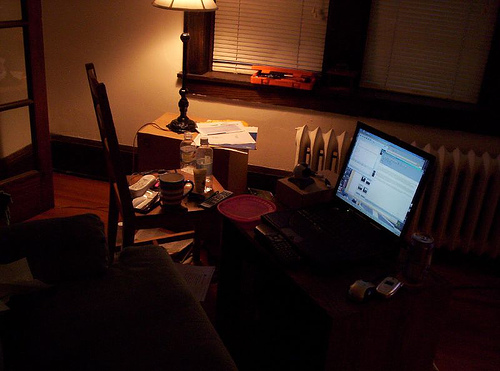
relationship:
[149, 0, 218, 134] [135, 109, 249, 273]
lamp on top of table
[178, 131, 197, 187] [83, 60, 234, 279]
bottle on top of chair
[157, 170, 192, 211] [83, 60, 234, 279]
coffee mug on top of chair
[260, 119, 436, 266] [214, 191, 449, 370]
laptop on top of desk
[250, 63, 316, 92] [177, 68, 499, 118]
tools sitting on window sill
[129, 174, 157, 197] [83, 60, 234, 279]
cordless phone on top of chair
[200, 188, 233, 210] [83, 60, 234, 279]
remote on top of chair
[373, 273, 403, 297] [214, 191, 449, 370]
cellphone on top of desk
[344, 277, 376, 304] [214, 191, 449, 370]
mouse on top of desk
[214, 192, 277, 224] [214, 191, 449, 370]
plate on top of desk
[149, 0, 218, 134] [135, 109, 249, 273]
lamp sitting on table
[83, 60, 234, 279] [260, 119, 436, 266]
chair next to laptop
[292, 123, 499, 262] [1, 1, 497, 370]
radiator inside of room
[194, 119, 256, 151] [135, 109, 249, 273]
papers on top of table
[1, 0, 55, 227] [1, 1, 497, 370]
door inside of room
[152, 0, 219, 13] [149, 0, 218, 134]
shade on top of lamp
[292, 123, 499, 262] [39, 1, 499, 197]
radiator mounted on wall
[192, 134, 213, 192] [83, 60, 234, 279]
bottle sitting on chair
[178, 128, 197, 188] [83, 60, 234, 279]
bottle sitting on chair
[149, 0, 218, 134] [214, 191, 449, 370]
lamp to left of desk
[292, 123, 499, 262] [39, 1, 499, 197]
radiator along wall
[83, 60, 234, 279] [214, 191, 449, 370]
chair left of desk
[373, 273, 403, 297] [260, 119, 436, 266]
cellphone next to laptop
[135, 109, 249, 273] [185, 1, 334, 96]
table underneath window